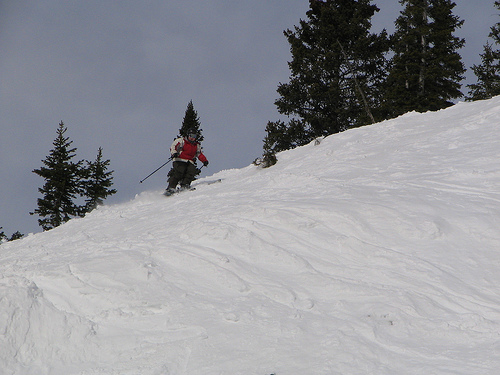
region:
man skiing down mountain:
[133, 118, 224, 225]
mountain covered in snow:
[107, 191, 453, 372]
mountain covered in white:
[155, 203, 437, 371]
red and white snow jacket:
[154, 140, 205, 165]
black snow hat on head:
[182, 128, 201, 143]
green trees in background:
[32, 112, 110, 224]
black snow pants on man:
[160, 165, 199, 190]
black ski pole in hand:
[135, 153, 177, 188]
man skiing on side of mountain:
[141, 113, 231, 214]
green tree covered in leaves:
[317, 0, 434, 122]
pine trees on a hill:
[35, 108, 161, 283]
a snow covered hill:
[23, 68, 476, 362]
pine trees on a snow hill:
[241, 7, 468, 169]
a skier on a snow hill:
[121, 93, 248, 226]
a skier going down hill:
[111, 63, 261, 263]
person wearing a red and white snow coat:
[143, 89, 237, 235]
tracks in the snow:
[49, 169, 423, 369]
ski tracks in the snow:
[81, 154, 434, 354]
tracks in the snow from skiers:
[83, 122, 457, 347]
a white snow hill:
[65, 100, 477, 372]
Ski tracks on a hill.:
[98, 241, 490, 361]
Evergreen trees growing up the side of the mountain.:
[24, 120, 118, 210]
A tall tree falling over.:
[324, 14, 385, 121]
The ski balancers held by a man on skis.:
[133, 153, 184, 185]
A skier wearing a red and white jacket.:
[164, 137, 209, 166]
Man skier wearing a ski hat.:
[181, 128, 201, 144]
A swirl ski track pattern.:
[409, 212, 464, 251]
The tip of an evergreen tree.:
[176, 97, 201, 114]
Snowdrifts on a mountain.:
[26, 270, 100, 336]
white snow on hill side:
[205, 232, 272, 290]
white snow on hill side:
[345, 169, 385, 217]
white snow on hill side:
[354, 265, 402, 305]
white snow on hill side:
[151, 211, 215, 293]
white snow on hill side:
[411, 168, 456, 259]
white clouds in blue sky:
[187, 0, 232, 55]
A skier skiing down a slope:
[133, 119, 214, 204]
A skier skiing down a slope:
[132, 121, 217, 211]